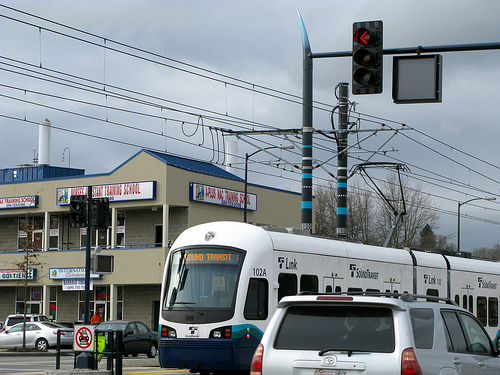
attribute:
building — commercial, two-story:
[5, 164, 203, 335]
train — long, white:
[151, 217, 497, 371]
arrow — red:
[352, 25, 379, 48]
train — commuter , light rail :
[121, 213, 498, 350]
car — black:
[80, 321, 167, 362]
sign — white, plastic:
[189, 182, 258, 212]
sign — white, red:
[47, 178, 157, 206]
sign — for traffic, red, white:
[71, 322, 95, 353]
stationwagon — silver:
[251, 291, 498, 373]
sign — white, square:
[73, 325, 103, 359]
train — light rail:
[110, 155, 404, 373]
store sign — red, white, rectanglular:
[186, 182, 257, 212]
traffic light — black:
[349, 19, 387, 92]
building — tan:
[0, 152, 300, 335]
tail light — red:
[245, 338, 265, 371]